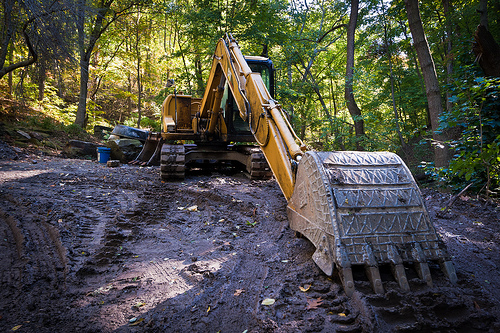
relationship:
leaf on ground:
[459, 190, 469, 197] [6, 141, 495, 331]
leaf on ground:
[234, 287, 248, 297] [22, 160, 467, 331]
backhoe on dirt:
[159, 32, 457, 297] [5, 150, 496, 329]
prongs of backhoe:
[334, 260, 459, 295] [159, 32, 457, 297]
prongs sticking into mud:
[334, 260, 459, 295] [3, 151, 494, 324]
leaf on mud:
[258, 297, 274, 307] [3, 151, 494, 324]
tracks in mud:
[3, 189, 108, 275] [3, 151, 494, 324]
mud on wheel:
[167, 144, 176, 179] [157, 143, 186, 182]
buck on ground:
[95, 145, 110, 162] [6, 141, 495, 331]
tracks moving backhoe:
[160, 140, 273, 184] [157, 33, 456, 293]